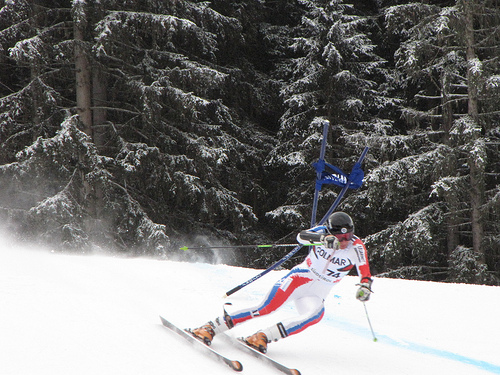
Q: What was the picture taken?
A: Morning.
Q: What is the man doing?
A: Skiing.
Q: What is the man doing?
A: Skiing.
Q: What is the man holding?
A: Skies.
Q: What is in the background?
A: Trees.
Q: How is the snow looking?
A: White.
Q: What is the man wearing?
A: Shirt.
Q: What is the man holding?
A: Poles.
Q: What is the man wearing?
A: Outfit.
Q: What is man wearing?
A: Jacket.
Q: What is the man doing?
A: Skiing.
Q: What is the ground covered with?
A: Snow.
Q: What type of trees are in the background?
A: Evergreen.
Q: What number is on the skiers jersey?
A: 74.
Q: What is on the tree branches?
A: Snow.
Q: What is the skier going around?
A: Ski gate.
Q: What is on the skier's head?
A: Helmet.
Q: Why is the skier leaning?
A: To turn around the gate.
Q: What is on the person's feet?
A: Skis.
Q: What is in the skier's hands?
A: Poles.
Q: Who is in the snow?
A: A man.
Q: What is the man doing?
A: Skiing.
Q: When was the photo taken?
A: Winter season.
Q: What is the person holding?
A: Ski poles.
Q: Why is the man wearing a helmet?
A: For protection.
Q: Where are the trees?
A: Behind the skier.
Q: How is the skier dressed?
A: In white and red.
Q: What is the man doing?
A: Sking.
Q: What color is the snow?
A: White.